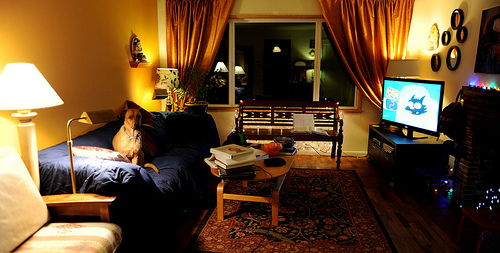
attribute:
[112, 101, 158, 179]
dog — laying, watching, sitting, looking, large, big, brown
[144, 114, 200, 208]
couch — here, long, big, blue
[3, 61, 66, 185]
lamp — bright, on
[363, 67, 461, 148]
tv — flat, black, close, on, smaller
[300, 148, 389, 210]
floor — wooden, brown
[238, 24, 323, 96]
window — black, clear, clean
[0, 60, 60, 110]
shade — white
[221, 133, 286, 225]
coffee table — brown, wooden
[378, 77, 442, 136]
television — flat-screen